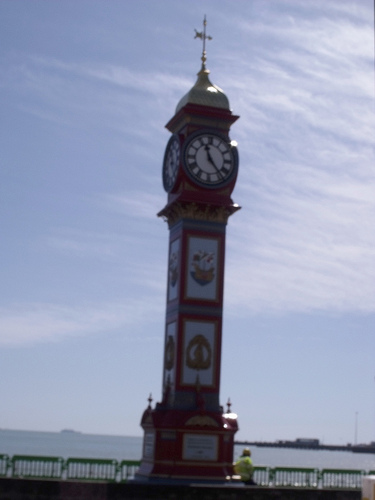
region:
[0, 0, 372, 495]
Daytime near the ocean.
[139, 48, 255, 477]
A skinny clock tower.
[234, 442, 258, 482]
A person sitting near the clock tower.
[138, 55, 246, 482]
The clock tower is red, white and gold.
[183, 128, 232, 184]
A clock on the tower.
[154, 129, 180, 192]
Another clock on the tower.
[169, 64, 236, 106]
The roof on the clock tower.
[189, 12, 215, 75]
A pole on top of the clock tower.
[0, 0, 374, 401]
Blue sky with wispy clouds.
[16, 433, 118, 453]
The ocean is blue.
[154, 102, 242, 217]
A high clock tower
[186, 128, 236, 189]
The clock facing away from the sea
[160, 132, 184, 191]
The clock facing away from the sun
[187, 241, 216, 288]
A drawing on the clock pillar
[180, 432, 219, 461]
A plaque on the base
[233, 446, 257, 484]
A person sitting on the its base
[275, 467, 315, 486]
A protection barrier with bars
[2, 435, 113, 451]
The blue sea in the background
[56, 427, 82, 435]
The silhouette of a ship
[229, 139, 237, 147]
A bright reflection on the tower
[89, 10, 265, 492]
a very tall clock tower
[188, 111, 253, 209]
the clock reads 23 minutes past 11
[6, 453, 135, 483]
a metal fence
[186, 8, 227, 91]
the clock tower has a weather vane on top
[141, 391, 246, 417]
pointed decorations are on the tower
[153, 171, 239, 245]
the tower is mostly red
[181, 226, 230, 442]
other pictures are painted on the tower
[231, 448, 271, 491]
a person sits at the bottom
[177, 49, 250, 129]
the top of the dome is white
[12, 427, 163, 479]
water is in the background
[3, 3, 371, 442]
the sunny sky above everything and the ocean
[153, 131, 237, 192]
the clocks near the top of the tower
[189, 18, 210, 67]
the weather vane on top of the tower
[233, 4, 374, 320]
some white clouds in the sky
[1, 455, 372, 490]
a fence at the end of the sidewalk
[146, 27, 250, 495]
a tall tower with clocks on it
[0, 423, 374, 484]
the ocean next to the fence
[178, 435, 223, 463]
a sign on the tower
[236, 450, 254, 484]
a person sitting by the tower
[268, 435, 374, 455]
a pier next to the ocean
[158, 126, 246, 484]
the tower is red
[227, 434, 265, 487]
the man is sitting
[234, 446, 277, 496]
the man is sitting